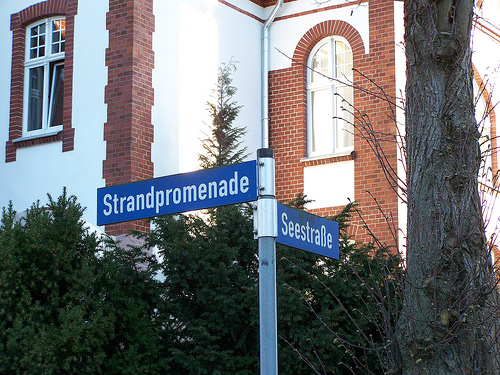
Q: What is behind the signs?
A: A building.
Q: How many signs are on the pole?
A: Two.